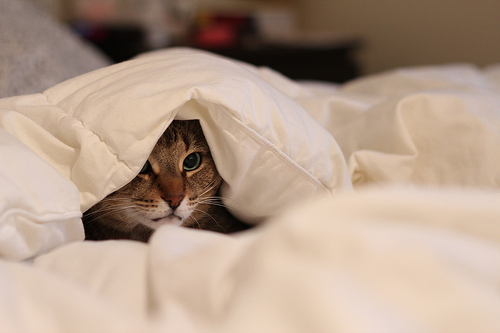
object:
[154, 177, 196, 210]
nose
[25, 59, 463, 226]
blanket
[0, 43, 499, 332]
sheets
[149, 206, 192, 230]
mouth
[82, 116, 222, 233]
cat`s head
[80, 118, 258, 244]
cat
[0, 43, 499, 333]
white blanket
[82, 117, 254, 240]
cat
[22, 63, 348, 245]
covers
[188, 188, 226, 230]
whiskers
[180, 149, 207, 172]
cat eyes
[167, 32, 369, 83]
desk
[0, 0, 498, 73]
background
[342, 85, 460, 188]
wrinkle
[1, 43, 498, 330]
blanket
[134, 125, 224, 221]
cat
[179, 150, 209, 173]
eye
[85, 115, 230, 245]
cat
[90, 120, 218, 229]
head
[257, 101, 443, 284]
blanket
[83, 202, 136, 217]
whisker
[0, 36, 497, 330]
covers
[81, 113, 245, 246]
cat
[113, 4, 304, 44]
objects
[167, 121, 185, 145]
stripes